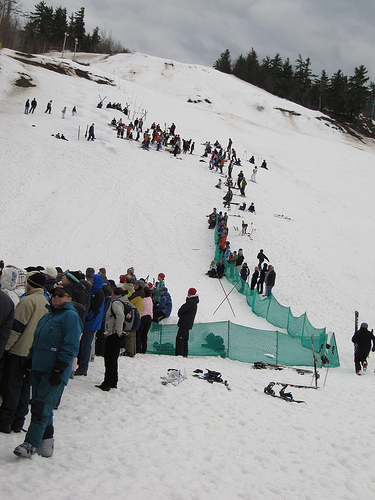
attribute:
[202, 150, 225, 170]
winter coat — grey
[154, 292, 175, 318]
coat — blue, grey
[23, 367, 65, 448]
snow pant — blue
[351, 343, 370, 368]
pants — black 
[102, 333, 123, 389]
pants — black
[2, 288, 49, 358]
coat — tan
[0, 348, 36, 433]
pants — black